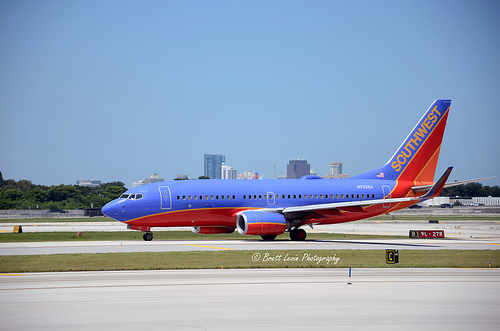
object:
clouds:
[56, 74, 96, 95]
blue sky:
[0, 0, 33, 73]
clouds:
[270, 115, 312, 131]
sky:
[61, 48, 105, 115]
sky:
[150, 3, 236, 16]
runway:
[0, 232, 492, 260]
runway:
[0, 264, 497, 329]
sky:
[333, 113, 345, 153]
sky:
[180, 69, 223, 105]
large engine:
[233, 206, 289, 237]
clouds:
[142, 70, 178, 89]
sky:
[314, 7, 349, 18]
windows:
[278, 190, 293, 203]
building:
[285, 156, 312, 178]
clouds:
[461, 0, 500, 49]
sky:
[62, 3, 139, 19]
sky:
[347, 40, 370, 74]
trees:
[0, 169, 130, 211]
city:
[64, 143, 371, 190]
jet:
[102, 96, 451, 245]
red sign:
[407, 230, 447, 239]